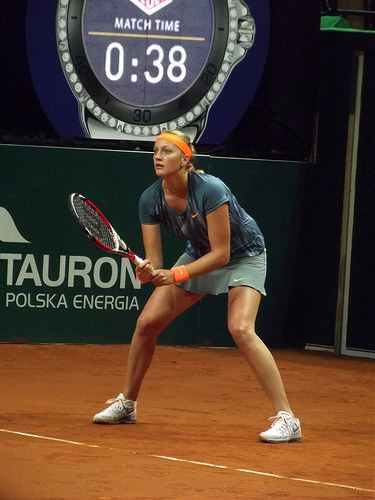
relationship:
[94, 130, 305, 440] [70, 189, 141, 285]
woman holding racket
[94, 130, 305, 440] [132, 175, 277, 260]
woman wearing shirt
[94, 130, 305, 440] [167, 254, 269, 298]
woman wearing skirt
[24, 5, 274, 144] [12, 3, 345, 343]
digital clock on wall